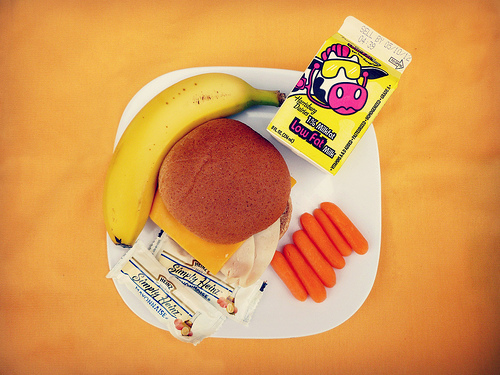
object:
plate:
[104, 66, 381, 341]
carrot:
[320, 202, 369, 255]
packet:
[104, 239, 227, 347]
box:
[265, 15, 412, 178]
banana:
[102, 73, 286, 249]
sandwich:
[149, 118, 296, 275]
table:
[0, 0, 500, 375]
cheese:
[149, 187, 246, 276]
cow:
[287, 42, 389, 116]